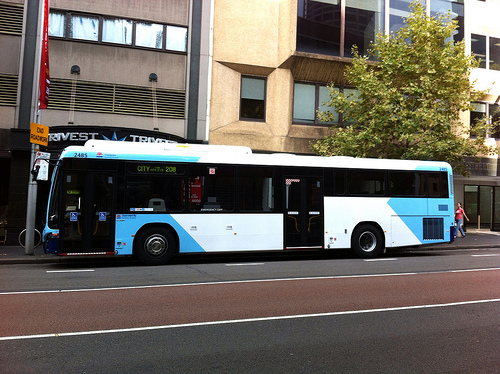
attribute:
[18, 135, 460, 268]
bus — blue, white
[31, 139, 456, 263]
bus — parked, white, blue